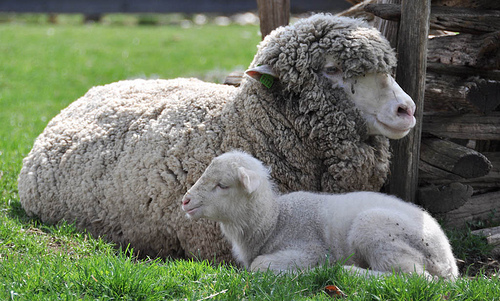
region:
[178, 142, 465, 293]
A white baby lamb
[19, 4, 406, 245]
A dirty white sheep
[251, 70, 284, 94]
A tag in the sheep's ear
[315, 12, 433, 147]
The white face of the lamb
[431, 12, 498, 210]
Stacks of wood next to the animals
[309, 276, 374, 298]
A piece of debris in the grass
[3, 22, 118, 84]
A bright green pasture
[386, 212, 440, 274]
Black spots on the lamb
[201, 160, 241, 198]
Lamb's closed eye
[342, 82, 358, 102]
A dirty spot on the sheep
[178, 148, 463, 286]
A young lamb laying down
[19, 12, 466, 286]
An adult lamb laying by a young lamb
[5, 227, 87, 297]
A patch of green grass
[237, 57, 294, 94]
The tagged ear of a sheep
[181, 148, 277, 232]
The head of a baby lamb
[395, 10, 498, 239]
A pile of wooden logs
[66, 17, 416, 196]
A woolly adult sheep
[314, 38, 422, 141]
The face of a sheep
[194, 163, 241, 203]
A young lamb's closed eye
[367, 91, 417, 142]
The muzzle of a sheep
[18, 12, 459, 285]
a mother sheep and her baby lamb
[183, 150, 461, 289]
a baby lamb laying in the grass field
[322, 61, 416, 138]
a sheep's white face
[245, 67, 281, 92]
the sheep's ear with an identification tag in it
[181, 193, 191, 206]
a baby lambs pink nose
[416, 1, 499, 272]
a wooden structure next to the lamb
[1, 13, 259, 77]
a grazing field for the sheep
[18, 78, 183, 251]
thick sheep wool on the sheep's back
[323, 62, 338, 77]
the sheep's black eye watching the photographer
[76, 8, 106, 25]
a black cow in the distance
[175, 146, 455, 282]
White lamb lay beside sheep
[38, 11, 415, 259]
sheep with thick wool coat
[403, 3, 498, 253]
grey weathered wooden fence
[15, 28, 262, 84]
empty field of green grass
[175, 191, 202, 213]
pink nose of lamb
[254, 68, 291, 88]
green tag in sheep ear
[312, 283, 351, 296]
brown leave on ground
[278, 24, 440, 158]
grey head of sheep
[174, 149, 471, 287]
a lamb is laying down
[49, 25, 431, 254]
sheep is laying down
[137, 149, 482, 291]
A lamb lying on the ground.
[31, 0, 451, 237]
A sheep lying behind the lamb.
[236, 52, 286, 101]
Tag in the sheep's ear.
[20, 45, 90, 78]
The grass is green.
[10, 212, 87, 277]
Dirt patch in the ground.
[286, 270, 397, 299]
Leaf on the ground.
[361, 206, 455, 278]
Dirt on the lamb.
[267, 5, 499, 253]
Wood next to the animals.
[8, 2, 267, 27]
Grey in the background.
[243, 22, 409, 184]
The sheep's head and neck are dark grey.